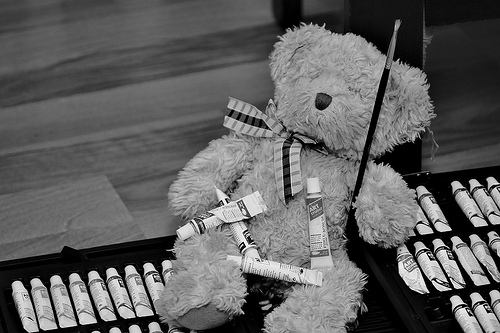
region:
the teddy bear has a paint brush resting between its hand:
[357, 15, 407, 224]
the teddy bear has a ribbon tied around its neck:
[224, 97, 311, 203]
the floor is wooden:
[43, 39, 193, 161]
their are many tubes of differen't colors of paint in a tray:
[6, 250, 151, 315]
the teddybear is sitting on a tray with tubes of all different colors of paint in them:
[173, 8, 418, 322]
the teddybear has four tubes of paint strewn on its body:
[175, 132, 332, 289]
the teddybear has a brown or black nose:
[311, 90, 333, 111]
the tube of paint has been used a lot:
[391, 249, 426, 296]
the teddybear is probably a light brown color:
[158, 17, 430, 330]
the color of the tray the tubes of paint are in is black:
[356, 250, 402, 326]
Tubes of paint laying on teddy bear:
[173, 179, 356, 288]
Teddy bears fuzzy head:
[285, 12, 420, 143]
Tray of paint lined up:
[7, 271, 111, 331]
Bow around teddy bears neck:
[227, 82, 322, 197]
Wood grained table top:
[33, 45, 220, 140]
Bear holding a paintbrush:
[365, 8, 409, 239]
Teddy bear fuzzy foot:
[152, 262, 232, 331]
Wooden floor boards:
[7, 98, 144, 225]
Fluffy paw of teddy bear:
[357, 171, 426, 271]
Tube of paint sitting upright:
[285, 170, 345, 267]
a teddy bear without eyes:
[168, 20, 436, 321]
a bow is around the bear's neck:
[221, 95, 369, 204]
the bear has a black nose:
[312, 90, 333, 111]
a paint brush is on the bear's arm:
[350, 15, 405, 215]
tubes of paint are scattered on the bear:
[175, 175, 336, 298]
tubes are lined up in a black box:
[11, 227, 250, 332]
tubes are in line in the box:
[376, 165, 498, 332]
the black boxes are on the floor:
[16, 12, 499, 329]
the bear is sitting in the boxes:
[159, 24, 429, 331]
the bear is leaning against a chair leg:
[234, 4, 433, 186]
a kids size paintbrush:
[336, 14, 412, 216]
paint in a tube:
[300, 175, 342, 271]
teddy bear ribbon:
[208, 73, 349, 189]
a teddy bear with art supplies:
[127, 14, 461, 331]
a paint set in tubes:
[2, 260, 245, 331]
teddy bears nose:
[295, 77, 355, 114]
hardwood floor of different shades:
[20, 42, 138, 223]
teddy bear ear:
[265, 14, 328, 92]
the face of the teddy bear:
[289, 25, 382, 142]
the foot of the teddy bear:
[152, 230, 249, 327]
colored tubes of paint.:
[350, 228, 477, 329]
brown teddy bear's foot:
[135, 294, 254, 329]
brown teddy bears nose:
[299, 85, 334, 140]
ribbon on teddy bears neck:
[161, 72, 360, 244]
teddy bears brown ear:
[365, 58, 442, 153]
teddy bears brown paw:
[339, 168, 427, 272]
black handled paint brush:
[335, 32, 407, 219]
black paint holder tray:
[0, 199, 170, 286]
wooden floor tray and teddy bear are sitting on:
[0, 137, 135, 241]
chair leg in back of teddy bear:
[246, 5, 318, 36]